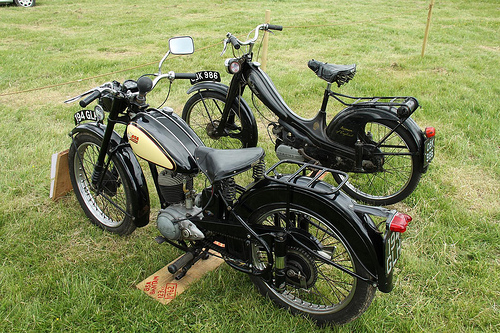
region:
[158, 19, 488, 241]
the bike is black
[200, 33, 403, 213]
the bike is black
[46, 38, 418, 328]
the bikes are parked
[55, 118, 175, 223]
the front wheel on a motorcycle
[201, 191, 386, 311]
the back wheel on a motorcycle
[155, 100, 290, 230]
the seat on a motorcycle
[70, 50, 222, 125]
the handlebars on a motorcycle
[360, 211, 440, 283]
the license plate on a motorcycle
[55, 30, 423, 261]
two motorcycles on grass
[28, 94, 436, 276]
a black motorcycle sitting on grss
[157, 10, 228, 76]
a mirror on a motorcycle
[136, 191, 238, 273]
the engine on a motorcycle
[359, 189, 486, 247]
the break light on a motorcycle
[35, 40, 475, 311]
two bikes on grass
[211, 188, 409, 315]
bikes have black wheels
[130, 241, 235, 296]
bikes sitting on wood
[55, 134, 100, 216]
wood in front of wheels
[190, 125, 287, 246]
bike has black seat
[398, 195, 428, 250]
red taillight on bike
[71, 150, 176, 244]
black spokes on wheels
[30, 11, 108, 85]
green and thick grass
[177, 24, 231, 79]
mirror on side of bike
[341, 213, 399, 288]
black and white license plate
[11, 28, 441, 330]
two old black motorcycles parked on the grass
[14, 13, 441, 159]
small wood post and a rope around the motorcycles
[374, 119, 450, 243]
two red break lights on motorcycles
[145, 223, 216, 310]
a piece of board underneath a motorcycle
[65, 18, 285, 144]
two handle bars on motorcycles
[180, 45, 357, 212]
two black seats on motorcycles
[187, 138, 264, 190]
a black seat on a motorcycle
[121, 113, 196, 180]
black and tan gas tank on a motorcycle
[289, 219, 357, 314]
spokes on a motorcycle wheel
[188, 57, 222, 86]
a black tag with white letters and numbers